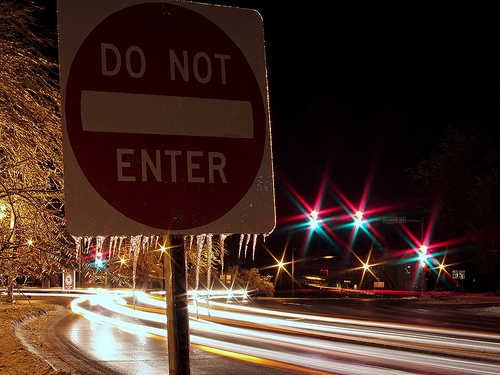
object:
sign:
[55, 1, 278, 241]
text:
[97, 41, 233, 90]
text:
[113, 145, 232, 192]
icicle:
[216, 231, 227, 275]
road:
[191, 295, 500, 374]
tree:
[0, 151, 62, 306]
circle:
[164, 11, 177, 18]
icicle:
[128, 238, 138, 309]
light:
[350, 210, 365, 230]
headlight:
[189, 286, 199, 299]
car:
[186, 281, 218, 307]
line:
[193, 341, 319, 375]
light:
[416, 242, 435, 262]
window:
[319, 267, 329, 277]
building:
[305, 254, 478, 292]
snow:
[17, 327, 29, 340]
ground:
[1, 298, 21, 374]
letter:
[213, 51, 235, 91]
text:
[185, 149, 205, 184]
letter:
[207, 152, 226, 186]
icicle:
[72, 239, 83, 260]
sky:
[276, 6, 497, 149]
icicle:
[192, 236, 204, 321]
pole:
[162, 240, 193, 372]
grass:
[0, 361, 35, 375]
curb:
[14, 307, 117, 375]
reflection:
[85, 319, 130, 359]